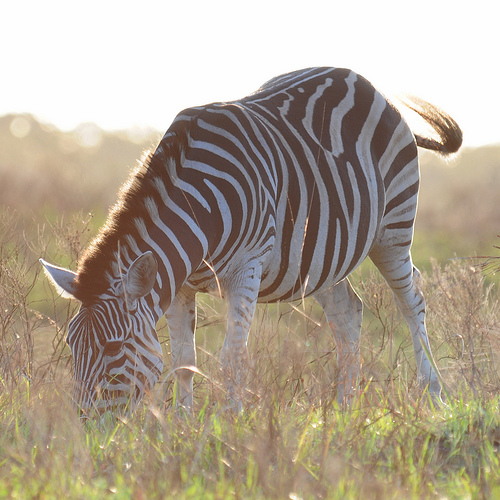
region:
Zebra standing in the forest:
[31, 75, 490, 468]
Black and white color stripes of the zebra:
[255, 143, 371, 256]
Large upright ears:
[38, 253, 176, 318]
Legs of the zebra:
[175, 315, 454, 427]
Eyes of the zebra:
[57, 330, 124, 360]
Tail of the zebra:
[411, 91, 467, 164]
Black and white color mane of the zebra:
[72, 127, 157, 278]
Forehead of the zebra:
[68, 319, 105, 349]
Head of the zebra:
[16, 243, 169, 443]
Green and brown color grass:
[287, 400, 426, 481]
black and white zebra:
[92, 96, 432, 392]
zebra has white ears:
[65, 224, 187, 309]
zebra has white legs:
[185, 277, 446, 422]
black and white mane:
[90, 113, 208, 281]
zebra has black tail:
[387, 71, 445, 170]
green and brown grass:
[132, 328, 447, 475]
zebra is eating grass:
[97, 42, 445, 453]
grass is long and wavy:
[295, 319, 465, 485]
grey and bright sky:
[106, 18, 186, 119]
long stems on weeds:
[5, 215, 105, 390]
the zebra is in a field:
[25, 58, 480, 485]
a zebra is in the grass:
[10, 31, 481, 401]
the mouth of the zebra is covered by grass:
[17, 223, 212, 465]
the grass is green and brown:
[16, 358, 489, 481]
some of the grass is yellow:
[0, 257, 495, 443]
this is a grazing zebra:
[16, 50, 498, 486]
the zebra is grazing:
[12, 40, 475, 436]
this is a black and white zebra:
[28, 72, 493, 469]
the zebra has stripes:
[10, 31, 495, 446]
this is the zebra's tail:
[376, 75, 481, 190]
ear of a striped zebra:
[120, 251, 162, 311]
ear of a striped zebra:
[35, 249, 83, 306]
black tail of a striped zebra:
[391, 92, 462, 164]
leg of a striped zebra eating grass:
[213, 251, 271, 419]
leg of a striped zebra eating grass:
[165, 287, 204, 428]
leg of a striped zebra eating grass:
[312, 279, 367, 410]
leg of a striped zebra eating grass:
[371, 208, 455, 411]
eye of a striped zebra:
[100, 334, 130, 362]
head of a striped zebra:
[33, 231, 188, 441]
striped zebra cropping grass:
[21, 52, 485, 489]